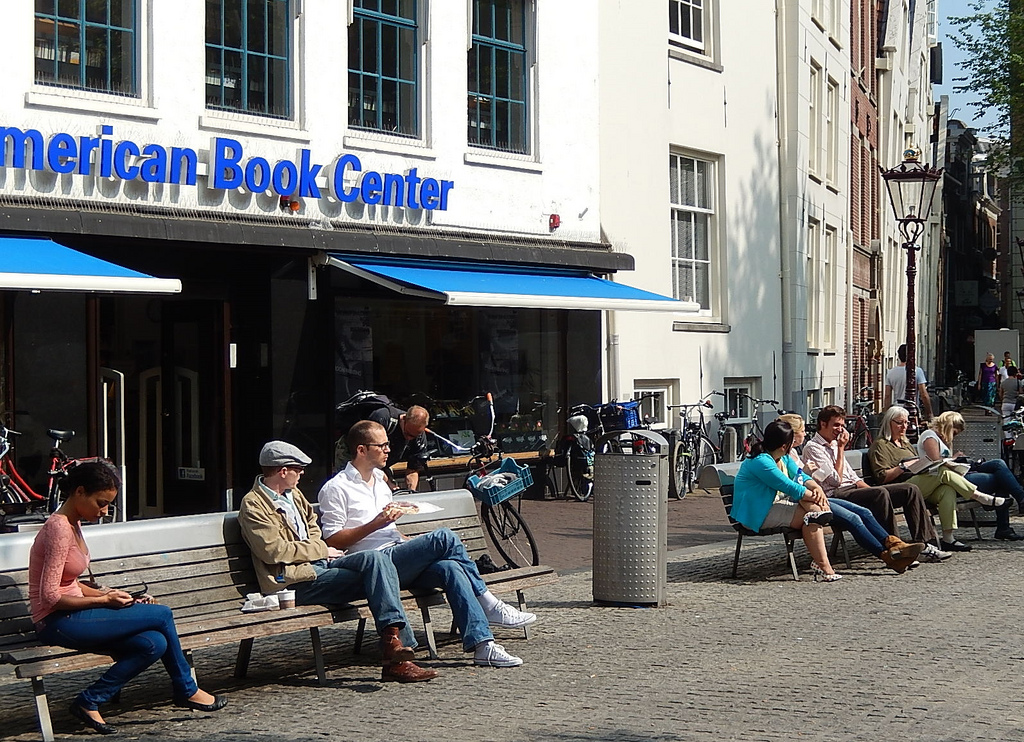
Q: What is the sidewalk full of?
A: Bikes.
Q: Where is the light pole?
A: On the right of the image.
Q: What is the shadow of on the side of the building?
A: A tree.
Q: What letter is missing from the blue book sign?
A: An A.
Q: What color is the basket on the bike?
A: Blue.